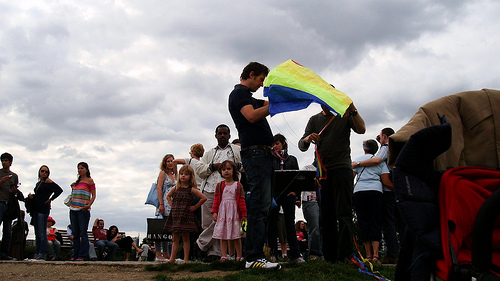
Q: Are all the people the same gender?
A: No, they are both male and female.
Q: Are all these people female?
A: No, they are both male and female.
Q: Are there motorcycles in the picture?
A: No, there are no motorcycles.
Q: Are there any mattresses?
A: No, there are no mattresses.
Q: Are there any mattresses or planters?
A: No, there are no mattresses or planters.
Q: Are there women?
A: Yes, there is a woman.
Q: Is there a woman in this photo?
A: Yes, there is a woman.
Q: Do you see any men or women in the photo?
A: Yes, there is a woman.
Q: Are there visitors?
A: No, there are no visitors.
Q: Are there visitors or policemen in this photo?
A: No, there are no visitors or policemen.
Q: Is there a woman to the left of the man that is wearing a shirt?
A: Yes, there is a woman to the left of the man.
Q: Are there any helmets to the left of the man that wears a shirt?
A: No, there is a woman to the left of the man.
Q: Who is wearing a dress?
A: The woman is wearing a dress.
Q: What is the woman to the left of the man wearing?
A: The woman is wearing a dress.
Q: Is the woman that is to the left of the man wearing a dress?
A: Yes, the woman is wearing a dress.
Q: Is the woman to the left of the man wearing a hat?
A: No, the woman is wearing a dress.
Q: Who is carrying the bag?
A: The woman is carrying the bag.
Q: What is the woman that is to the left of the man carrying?
A: The woman is carrying a bag.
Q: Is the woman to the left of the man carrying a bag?
A: Yes, the woman is carrying a bag.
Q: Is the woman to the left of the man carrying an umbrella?
A: No, the woman is carrying a bag.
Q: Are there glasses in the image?
A: No, there are no glasses.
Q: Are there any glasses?
A: No, there are no glasses.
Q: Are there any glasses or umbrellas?
A: No, there are no glasses or umbrellas.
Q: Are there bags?
A: Yes, there is a bag.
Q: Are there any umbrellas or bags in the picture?
A: Yes, there is a bag.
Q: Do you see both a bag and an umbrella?
A: No, there is a bag but no umbrellas.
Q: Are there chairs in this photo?
A: No, there are no chairs.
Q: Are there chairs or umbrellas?
A: No, there are no chairs or umbrellas.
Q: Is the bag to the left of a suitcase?
A: No, the bag is to the left of a girl.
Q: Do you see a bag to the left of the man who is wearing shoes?
A: Yes, there is a bag to the left of the man.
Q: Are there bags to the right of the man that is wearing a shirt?
A: No, the bag is to the left of the man.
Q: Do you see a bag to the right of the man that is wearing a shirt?
A: No, the bag is to the left of the man.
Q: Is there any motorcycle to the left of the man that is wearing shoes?
A: No, there is a bag to the left of the man.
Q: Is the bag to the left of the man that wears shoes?
A: Yes, the bag is to the left of the man.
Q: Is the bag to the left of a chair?
A: No, the bag is to the left of the man.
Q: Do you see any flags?
A: Yes, there is a flag.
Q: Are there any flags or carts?
A: Yes, there is a flag.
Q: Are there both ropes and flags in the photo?
A: No, there is a flag but no ropes.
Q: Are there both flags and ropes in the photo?
A: No, there is a flag but no ropes.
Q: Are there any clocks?
A: No, there are no clocks.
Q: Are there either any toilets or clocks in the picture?
A: No, there are no clocks or toilets.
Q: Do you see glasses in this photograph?
A: No, there are no glasses.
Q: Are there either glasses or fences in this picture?
A: No, there are no glasses or fences.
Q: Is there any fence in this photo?
A: No, there are no fences.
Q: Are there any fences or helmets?
A: No, there are no fences or helmets.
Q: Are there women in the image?
A: Yes, there is a woman.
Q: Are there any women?
A: Yes, there is a woman.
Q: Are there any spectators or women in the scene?
A: Yes, there is a woman.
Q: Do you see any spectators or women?
A: Yes, there is a woman.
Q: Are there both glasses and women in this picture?
A: No, there is a woman but no glasses.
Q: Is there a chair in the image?
A: No, there are no chairs.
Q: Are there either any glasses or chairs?
A: No, there are no chairs or glasses.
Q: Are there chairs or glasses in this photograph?
A: No, there are no chairs or glasses.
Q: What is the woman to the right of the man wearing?
A: The woman is wearing shirts.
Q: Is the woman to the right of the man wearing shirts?
A: Yes, the woman is wearing shirts.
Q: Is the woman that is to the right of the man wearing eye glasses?
A: No, the woman is wearing shirts.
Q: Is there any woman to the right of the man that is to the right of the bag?
A: Yes, there is a woman to the right of the man.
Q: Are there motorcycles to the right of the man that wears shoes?
A: No, there is a woman to the right of the man.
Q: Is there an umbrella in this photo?
A: No, there are no umbrellas.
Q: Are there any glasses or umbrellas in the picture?
A: No, there are no umbrellas or glasses.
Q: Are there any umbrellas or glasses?
A: No, there are no umbrellas or glasses.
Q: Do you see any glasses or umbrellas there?
A: No, there are no umbrellas or glasses.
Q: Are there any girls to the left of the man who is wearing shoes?
A: Yes, there is a girl to the left of the man.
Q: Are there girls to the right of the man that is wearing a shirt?
A: No, the girl is to the left of the man.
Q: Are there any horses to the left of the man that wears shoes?
A: No, there is a girl to the left of the man.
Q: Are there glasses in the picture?
A: No, there are no glasses.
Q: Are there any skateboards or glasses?
A: No, there are no glasses or skateboards.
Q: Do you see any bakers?
A: No, there are no bakers.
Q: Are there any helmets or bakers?
A: No, there are no bakers or helmets.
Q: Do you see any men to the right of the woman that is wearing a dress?
A: Yes, there is a man to the right of the woman.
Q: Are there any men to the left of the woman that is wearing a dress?
A: No, the man is to the right of the woman.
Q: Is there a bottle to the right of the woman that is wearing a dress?
A: No, there is a man to the right of the woman.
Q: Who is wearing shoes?
A: The man is wearing shoes.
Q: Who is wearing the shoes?
A: The man is wearing shoes.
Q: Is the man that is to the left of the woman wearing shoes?
A: Yes, the man is wearing shoes.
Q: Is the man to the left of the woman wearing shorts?
A: No, the man is wearing shoes.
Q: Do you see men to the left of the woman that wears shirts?
A: Yes, there is a man to the left of the woman.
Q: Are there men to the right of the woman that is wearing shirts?
A: No, the man is to the left of the woman.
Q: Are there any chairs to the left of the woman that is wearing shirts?
A: No, there is a man to the left of the woman.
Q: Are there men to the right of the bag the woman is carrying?
A: Yes, there is a man to the right of the bag.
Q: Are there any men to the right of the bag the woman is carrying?
A: Yes, there is a man to the right of the bag.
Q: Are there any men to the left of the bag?
A: No, the man is to the right of the bag.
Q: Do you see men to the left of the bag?
A: No, the man is to the right of the bag.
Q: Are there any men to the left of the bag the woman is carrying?
A: No, the man is to the right of the bag.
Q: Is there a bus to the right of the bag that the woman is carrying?
A: No, there is a man to the right of the bag.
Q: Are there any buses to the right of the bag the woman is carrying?
A: No, there is a man to the right of the bag.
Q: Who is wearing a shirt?
A: The man is wearing a shirt.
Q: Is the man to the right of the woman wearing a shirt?
A: Yes, the man is wearing a shirt.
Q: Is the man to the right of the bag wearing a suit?
A: No, the man is wearing a shirt.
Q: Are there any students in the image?
A: No, there are no students.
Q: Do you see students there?
A: No, there are no students.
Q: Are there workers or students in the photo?
A: No, there are no students or workers.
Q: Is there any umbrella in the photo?
A: No, there are no umbrellas.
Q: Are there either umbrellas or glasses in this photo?
A: No, there are no umbrellas or glasses.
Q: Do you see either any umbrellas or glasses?
A: No, there are no umbrellas or glasses.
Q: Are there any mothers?
A: No, there are no mothers.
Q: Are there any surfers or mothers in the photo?
A: No, there are no mothers or surfers.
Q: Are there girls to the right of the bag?
A: Yes, there is a girl to the right of the bag.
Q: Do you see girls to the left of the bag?
A: No, the girl is to the right of the bag.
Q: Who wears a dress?
A: The girl wears a dress.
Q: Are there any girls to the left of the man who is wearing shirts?
A: Yes, there is a girl to the left of the man.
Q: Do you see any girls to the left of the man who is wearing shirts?
A: Yes, there is a girl to the left of the man.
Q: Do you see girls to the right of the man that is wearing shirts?
A: No, the girl is to the left of the man.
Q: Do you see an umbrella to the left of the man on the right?
A: No, there is a girl to the left of the man.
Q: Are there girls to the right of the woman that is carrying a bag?
A: Yes, there is a girl to the right of the woman.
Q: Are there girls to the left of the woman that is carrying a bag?
A: No, the girl is to the right of the woman.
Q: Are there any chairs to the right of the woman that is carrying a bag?
A: No, there is a girl to the right of the woman.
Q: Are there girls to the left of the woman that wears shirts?
A: Yes, there is a girl to the left of the woman.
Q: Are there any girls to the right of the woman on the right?
A: No, the girl is to the left of the woman.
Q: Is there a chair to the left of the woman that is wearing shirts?
A: No, there is a girl to the left of the woman.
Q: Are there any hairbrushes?
A: No, there are no hairbrushes.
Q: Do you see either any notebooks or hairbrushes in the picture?
A: No, there are no hairbrushes or notebooks.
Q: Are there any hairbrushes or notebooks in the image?
A: No, there are no hairbrushes or notebooks.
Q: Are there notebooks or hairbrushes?
A: No, there are no hairbrushes or notebooks.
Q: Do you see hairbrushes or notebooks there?
A: No, there are no hairbrushes or notebooks.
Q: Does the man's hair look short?
A: Yes, the hair is short.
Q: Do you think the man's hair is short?
A: Yes, the hair is short.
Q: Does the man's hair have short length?
A: Yes, the hair is short.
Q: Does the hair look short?
A: Yes, the hair is short.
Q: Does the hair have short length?
A: Yes, the hair is short.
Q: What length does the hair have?
A: The hair has short length.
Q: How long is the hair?
A: The hair is short.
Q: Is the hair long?
A: No, the hair is short.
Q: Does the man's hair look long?
A: No, the hair is short.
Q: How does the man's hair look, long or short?
A: The hair is short.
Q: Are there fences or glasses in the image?
A: No, there are no glasses or fences.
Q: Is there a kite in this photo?
A: Yes, there is a kite.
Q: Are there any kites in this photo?
A: Yes, there is a kite.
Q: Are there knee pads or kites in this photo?
A: Yes, there is a kite.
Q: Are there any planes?
A: No, there are no planes.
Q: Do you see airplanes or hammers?
A: No, there are no airplanes or hammers.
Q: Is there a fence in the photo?
A: No, there are no fences.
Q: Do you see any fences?
A: No, there are no fences.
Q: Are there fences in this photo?
A: No, there are no fences.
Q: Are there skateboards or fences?
A: No, there are no fences or skateboards.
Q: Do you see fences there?
A: No, there are no fences.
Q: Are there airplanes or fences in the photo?
A: No, there are no fences or airplanes.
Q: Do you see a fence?
A: No, there are no fences.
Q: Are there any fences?
A: No, there are no fences.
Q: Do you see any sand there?
A: Yes, there is sand.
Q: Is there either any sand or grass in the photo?
A: Yes, there is sand.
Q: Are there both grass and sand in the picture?
A: Yes, there are both sand and grass.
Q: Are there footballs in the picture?
A: No, there are no footballs.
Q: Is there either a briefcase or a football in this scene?
A: No, there are no footballs or briefcases.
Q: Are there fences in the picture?
A: No, there are no fences.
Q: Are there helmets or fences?
A: No, there are no fences or helmets.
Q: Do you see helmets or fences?
A: No, there are no fences or helmets.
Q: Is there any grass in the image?
A: Yes, there is grass.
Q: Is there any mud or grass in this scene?
A: Yes, there is grass.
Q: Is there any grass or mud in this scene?
A: Yes, there is grass.